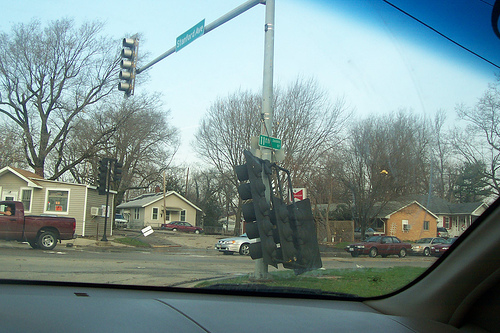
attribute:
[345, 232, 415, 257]
car — red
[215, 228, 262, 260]
car — silver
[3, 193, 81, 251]
truck — red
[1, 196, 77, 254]
truck — red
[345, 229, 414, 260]
car — fully visible, red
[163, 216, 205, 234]
car — red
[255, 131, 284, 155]
road sign — green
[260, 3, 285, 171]
post — vertical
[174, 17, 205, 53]
road sign — green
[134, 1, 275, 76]
post — vertical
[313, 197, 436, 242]
building — brick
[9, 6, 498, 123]
sky — cloudy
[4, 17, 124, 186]
tree — barren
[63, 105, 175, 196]
tree — barren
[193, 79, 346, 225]
tree — barren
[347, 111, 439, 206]
tree — barren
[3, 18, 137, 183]
tree — barren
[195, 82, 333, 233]
tree — barren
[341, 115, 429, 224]
tree — barren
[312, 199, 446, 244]
house — red, brick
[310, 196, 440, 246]
house — red, brick